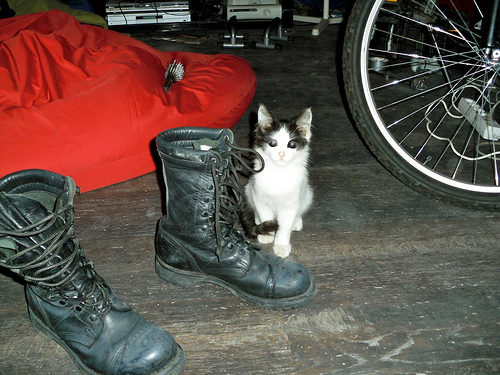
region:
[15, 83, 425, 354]
a cute cat near some work boots.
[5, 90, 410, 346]
a loveable cat near some work boots.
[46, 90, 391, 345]
an adorable cat near some work boots.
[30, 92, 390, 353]
an attractive cat near some work boots.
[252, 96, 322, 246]
a really precious cat.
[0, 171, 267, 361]
pair of dark work boots.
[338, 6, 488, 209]
part of a bicycle wheel.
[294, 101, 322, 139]
left ear of a cat.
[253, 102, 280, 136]
right ear of cat.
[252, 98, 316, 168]
head of a cat.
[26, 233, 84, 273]
black laces in a boot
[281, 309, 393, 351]
scratches on the floor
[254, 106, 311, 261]
a black and white kitten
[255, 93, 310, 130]
pointy ears on a head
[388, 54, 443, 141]
metal spokes on a bike wheel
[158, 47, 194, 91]
a hairbrush on a red futon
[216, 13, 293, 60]
push pup bars on the floor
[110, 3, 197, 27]
a stereo sitting on a low shelf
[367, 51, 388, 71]
a roll of gray duct tape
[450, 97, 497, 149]
a white surge protector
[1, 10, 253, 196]
Brush on top of red bean bag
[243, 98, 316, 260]
Cute little white kitten with black and tan on it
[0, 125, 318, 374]
Black work boots with black laces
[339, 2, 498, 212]
Bicycle wheel with white stripe on it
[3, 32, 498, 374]
Old wooden beat up floor with scratches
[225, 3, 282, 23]
Xbox 360 game system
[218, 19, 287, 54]
Workout weights for exercising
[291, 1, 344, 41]
Base of standing white fan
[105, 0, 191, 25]
Stereo equipment in background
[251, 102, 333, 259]
A black and white cat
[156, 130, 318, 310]
A black boot on an old wooden floor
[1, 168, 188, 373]
Another black boot on the wooden floor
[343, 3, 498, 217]
The wheel of a bicycle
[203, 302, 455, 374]
A scuffed and dirty area of the floor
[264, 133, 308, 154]
The cat's eyes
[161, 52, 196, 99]
A black and white object on a red pillow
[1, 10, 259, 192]
A red pillow on the floor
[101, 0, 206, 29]
A rectangular object with wires and a hole in the front in the background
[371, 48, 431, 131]
Spokes in the bicycle wheel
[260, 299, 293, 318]
sole of a boot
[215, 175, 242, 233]
laces of a boot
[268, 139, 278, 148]
right eye of a cat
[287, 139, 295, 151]
left eye of a cat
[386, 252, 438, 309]
part of a floor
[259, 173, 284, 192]
chest of a cat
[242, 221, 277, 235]
part of a cat's tail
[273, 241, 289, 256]
left paw of a cat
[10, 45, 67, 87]
part of a red material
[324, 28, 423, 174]
part of a wheel